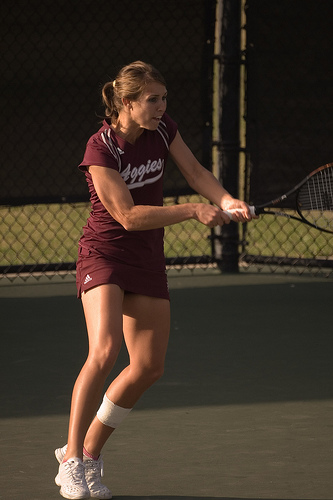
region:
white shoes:
[48, 458, 95, 498]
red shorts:
[80, 250, 138, 289]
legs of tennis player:
[79, 301, 157, 451]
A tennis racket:
[249, 183, 330, 228]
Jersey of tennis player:
[106, 142, 170, 199]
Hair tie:
[109, 77, 120, 86]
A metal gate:
[8, 84, 78, 217]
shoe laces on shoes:
[72, 458, 85, 484]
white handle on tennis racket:
[223, 209, 254, 227]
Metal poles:
[213, 7, 260, 169]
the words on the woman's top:
[120, 159, 164, 183]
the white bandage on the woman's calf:
[97, 395, 128, 427]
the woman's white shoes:
[53, 440, 110, 498]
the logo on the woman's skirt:
[83, 273, 92, 283]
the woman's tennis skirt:
[73, 237, 172, 300]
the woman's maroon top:
[78, 117, 181, 255]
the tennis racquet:
[222, 160, 331, 238]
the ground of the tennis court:
[164, 411, 320, 483]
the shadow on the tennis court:
[189, 297, 331, 370]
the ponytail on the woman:
[102, 79, 116, 120]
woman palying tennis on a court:
[22, 41, 324, 497]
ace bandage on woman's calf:
[98, 389, 132, 428]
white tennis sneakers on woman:
[29, 444, 116, 499]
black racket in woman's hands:
[218, 172, 331, 243]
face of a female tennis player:
[90, 57, 180, 136]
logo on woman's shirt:
[117, 152, 174, 200]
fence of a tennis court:
[18, 206, 66, 267]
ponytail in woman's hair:
[96, 75, 126, 121]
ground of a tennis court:
[161, 425, 306, 486]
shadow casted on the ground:
[198, 301, 298, 402]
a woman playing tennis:
[24, 69, 330, 495]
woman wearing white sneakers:
[44, 440, 116, 498]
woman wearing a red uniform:
[83, 126, 186, 299]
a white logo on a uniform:
[117, 154, 172, 192]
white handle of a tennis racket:
[214, 190, 260, 228]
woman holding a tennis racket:
[196, 161, 329, 243]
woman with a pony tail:
[93, 60, 174, 136]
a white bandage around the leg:
[89, 391, 147, 435]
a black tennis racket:
[251, 147, 330, 242]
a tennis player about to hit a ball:
[48, 62, 307, 499]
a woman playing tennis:
[66, 152, 136, 286]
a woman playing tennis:
[66, 152, 219, 464]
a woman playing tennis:
[57, 168, 161, 333]